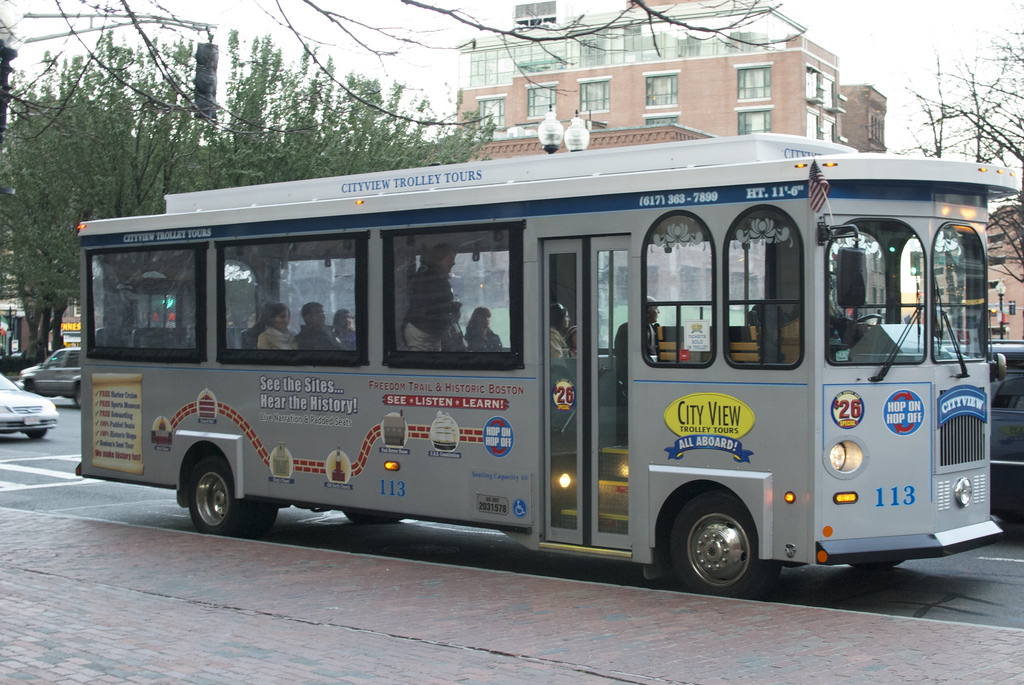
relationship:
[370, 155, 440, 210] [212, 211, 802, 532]
trolley written on trolley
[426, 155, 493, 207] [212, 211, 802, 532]
tours written on trolley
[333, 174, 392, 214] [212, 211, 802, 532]
cityview written on trolley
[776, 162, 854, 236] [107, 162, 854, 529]
flag on trolley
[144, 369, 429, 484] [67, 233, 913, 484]
map on side of trolley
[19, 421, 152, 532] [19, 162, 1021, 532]
crosswalk behind trolley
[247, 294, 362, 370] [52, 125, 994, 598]
people sitting on trolley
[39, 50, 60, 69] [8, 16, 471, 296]
leaves on tree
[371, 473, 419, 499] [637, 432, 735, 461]
wave on water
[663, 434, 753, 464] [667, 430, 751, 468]
water on water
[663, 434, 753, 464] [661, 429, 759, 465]
water on water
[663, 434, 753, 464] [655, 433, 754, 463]
water on water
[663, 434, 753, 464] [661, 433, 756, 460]
water on water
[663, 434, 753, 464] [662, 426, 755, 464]
water on water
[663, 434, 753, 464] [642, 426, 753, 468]
water on water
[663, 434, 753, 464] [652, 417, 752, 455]
water on water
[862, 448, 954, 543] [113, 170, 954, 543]
113 written on trolley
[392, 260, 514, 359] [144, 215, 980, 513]
person standing on trolley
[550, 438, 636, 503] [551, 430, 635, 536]
lights on steps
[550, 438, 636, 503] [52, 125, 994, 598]
lights on trolley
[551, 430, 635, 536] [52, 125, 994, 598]
steps on trolley